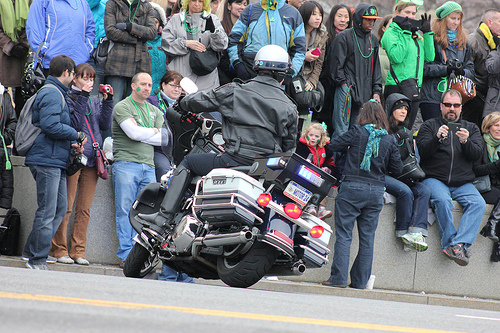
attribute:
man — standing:
[105, 66, 168, 271]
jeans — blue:
[415, 179, 487, 246]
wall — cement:
[0, 148, 499, 308]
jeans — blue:
[30, 162, 68, 263]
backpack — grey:
[13, 92, 46, 160]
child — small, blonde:
[301, 111, 358, 180]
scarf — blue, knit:
[355, 120, 390, 174]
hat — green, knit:
[437, 5, 459, 15]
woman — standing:
[49, 58, 113, 260]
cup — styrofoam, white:
[342, 252, 394, 288]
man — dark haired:
[15, 44, 83, 222]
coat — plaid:
[100, 0, 160, 80]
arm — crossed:
[102, 0, 138, 44]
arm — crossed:
[126, 3, 159, 41]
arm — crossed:
[112, 103, 157, 143]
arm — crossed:
[141, 110, 169, 147]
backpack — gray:
[11, 80, 67, 156]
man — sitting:
[416, 87, 485, 267]